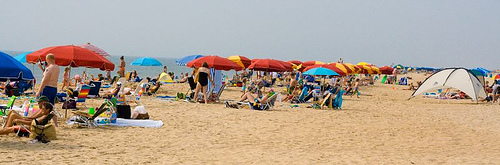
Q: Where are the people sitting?
A: Beach.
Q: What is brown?
A: Sand.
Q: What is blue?
A: Sky.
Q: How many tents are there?
A: One.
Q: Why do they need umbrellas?
A: It is sunny.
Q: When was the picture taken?
A: Daytime.